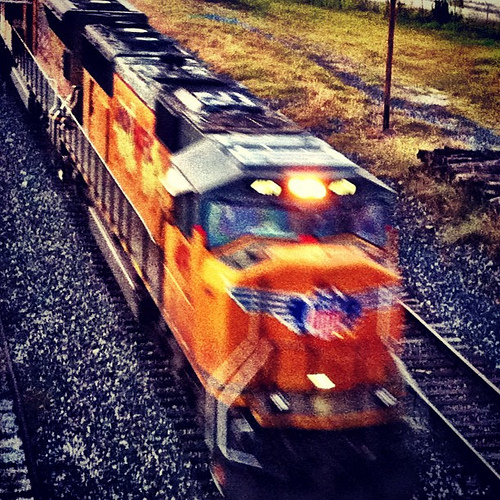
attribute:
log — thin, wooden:
[372, 3, 404, 138]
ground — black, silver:
[206, 32, 493, 175]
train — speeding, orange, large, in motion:
[9, 1, 436, 431]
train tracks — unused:
[385, 287, 497, 499]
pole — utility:
[381, 0, 398, 127]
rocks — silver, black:
[57, 357, 129, 432]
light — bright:
[279, 175, 331, 215]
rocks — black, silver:
[56, 272, 109, 397]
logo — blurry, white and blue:
[205, 279, 383, 356]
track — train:
[372, 294, 499, 497]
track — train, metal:
[389, 323, 497, 451]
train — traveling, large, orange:
[1, 2, 455, 489]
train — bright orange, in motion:
[10, 53, 438, 498]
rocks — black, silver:
[20, 256, 109, 400]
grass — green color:
[395, 35, 477, 113]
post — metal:
[382, 0, 397, 130]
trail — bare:
[218, 11, 468, 145]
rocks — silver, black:
[9, 246, 106, 478]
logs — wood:
[417, 136, 499, 166]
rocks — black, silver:
[391, 194, 498, 431]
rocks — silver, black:
[38, 359, 158, 486]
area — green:
[139, 4, 480, 205]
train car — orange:
[82, 22, 415, 449]